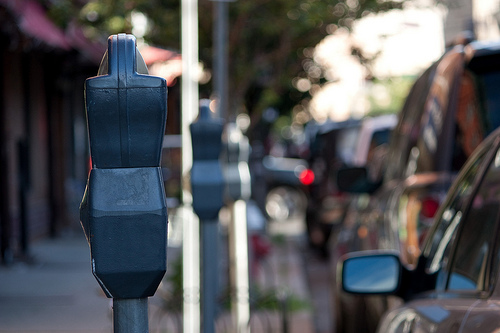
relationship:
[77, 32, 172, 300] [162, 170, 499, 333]
meter on street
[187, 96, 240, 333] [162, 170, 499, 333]
meter on street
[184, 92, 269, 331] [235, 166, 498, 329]
meter on street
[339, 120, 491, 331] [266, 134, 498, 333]
car parked on street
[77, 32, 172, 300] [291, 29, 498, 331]
meter along road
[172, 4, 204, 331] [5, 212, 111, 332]
pole on sidewalk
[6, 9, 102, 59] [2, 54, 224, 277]
roof on building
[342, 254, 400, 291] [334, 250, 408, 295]
glass in glass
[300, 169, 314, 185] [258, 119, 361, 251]
circle glare on truck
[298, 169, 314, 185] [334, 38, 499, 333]
circle glare on cars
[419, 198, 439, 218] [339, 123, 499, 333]
circle on one side of car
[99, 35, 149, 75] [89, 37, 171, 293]
meter top on meter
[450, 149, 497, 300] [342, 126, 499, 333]
window on back of car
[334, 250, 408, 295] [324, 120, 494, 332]
glass on side of car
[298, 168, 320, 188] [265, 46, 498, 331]
light of cars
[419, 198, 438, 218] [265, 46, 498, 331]
light of cars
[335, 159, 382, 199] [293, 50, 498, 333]
sideview mirror of cars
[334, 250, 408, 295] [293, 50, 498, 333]
glass of cars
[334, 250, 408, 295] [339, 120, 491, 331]
glass on car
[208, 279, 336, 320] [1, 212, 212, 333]
grass growing through sidewalk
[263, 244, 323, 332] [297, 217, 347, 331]
curb along street